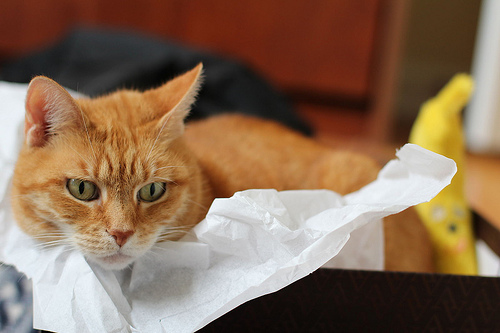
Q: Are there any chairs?
A: No, there are no chairs.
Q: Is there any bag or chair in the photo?
A: No, there are no chairs or bags.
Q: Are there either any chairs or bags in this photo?
A: No, there are no chairs or bags.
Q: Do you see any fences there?
A: No, there are no fences.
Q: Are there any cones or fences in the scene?
A: No, there are no fences or cones.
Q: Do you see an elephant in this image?
A: No, there are no elephants.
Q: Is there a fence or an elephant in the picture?
A: No, there are no elephants or fences.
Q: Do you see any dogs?
A: No, there are no dogs.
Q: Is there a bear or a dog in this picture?
A: No, there are no dogs or bears.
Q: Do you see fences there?
A: No, there are no fences.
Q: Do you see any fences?
A: No, there are no fences.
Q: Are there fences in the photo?
A: No, there are no fences.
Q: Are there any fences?
A: No, there are no fences.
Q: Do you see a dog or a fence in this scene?
A: No, there are no fences or dogs.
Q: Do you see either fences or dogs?
A: No, there are no fences or dogs.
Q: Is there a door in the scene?
A: Yes, there is a door.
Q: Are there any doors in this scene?
A: Yes, there is a door.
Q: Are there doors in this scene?
A: Yes, there is a door.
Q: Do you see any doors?
A: Yes, there is a door.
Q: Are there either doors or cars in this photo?
A: Yes, there is a door.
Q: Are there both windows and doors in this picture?
A: No, there is a door but no windows.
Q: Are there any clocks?
A: No, there are no clocks.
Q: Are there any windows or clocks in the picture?
A: No, there are no clocks or windows.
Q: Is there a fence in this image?
A: No, there are no fences.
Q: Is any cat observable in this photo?
A: Yes, there is a cat.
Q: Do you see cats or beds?
A: Yes, there is a cat.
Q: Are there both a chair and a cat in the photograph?
A: No, there is a cat but no chairs.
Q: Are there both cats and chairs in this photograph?
A: No, there is a cat but no chairs.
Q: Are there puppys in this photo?
A: No, there are no puppys.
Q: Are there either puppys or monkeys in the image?
A: No, there are no puppys or monkeys.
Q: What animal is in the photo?
A: The animal is a cat.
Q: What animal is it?
A: The animal is a cat.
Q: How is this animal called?
A: This is a cat.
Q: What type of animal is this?
A: This is a cat.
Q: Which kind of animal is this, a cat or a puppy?
A: This is a cat.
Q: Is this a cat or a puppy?
A: This is a cat.